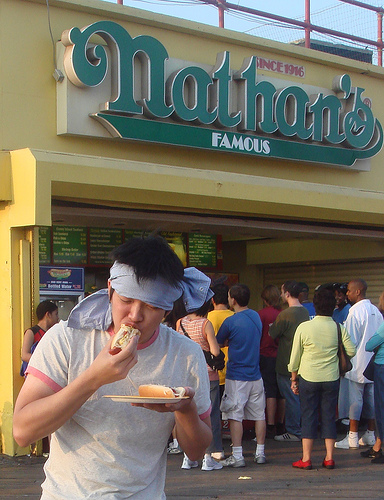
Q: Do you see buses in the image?
A: No, there are no buses.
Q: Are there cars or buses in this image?
A: No, there are no buses or cars.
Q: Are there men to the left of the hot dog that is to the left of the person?
A: Yes, there is a man to the left of the hot dog.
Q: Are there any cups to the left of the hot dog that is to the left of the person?
A: No, there is a man to the left of the hot dog.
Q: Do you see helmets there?
A: No, there are no helmets.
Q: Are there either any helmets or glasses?
A: No, there are no helmets or glasses.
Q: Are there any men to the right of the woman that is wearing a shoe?
A: Yes, there is a man to the right of the woman.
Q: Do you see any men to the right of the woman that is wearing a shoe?
A: Yes, there is a man to the right of the woman.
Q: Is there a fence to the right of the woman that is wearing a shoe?
A: No, there is a man to the right of the woman.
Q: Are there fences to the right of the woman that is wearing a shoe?
A: No, there is a man to the right of the woman.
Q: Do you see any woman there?
A: Yes, there is a woman.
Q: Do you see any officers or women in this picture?
A: Yes, there is a woman.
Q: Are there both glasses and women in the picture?
A: No, there is a woman but no glasses.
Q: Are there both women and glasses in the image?
A: No, there is a woman but no glasses.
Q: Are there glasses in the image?
A: No, there are no glasses.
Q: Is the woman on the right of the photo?
A: Yes, the woman is on the right of the image.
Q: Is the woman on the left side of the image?
A: No, the woman is on the right of the image.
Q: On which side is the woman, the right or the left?
A: The woman is on the right of the image.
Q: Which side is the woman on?
A: The woman is on the right of the image.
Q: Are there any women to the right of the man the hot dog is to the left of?
A: Yes, there is a woman to the right of the man.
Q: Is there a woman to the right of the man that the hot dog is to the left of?
A: Yes, there is a woman to the right of the man.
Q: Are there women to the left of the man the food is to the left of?
A: No, the woman is to the right of the man.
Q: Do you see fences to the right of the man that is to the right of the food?
A: No, there is a woman to the right of the man.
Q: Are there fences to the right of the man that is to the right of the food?
A: No, there is a woman to the right of the man.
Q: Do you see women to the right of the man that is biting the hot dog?
A: Yes, there is a woman to the right of the man.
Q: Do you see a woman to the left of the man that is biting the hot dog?
A: No, the woman is to the right of the man.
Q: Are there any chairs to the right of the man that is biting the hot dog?
A: No, there is a woman to the right of the man.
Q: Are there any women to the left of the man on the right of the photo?
A: Yes, there is a woman to the left of the man.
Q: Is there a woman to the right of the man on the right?
A: No, the woman is to the left of the man.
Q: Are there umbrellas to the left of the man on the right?
A: No, there is a woman to the left of the man.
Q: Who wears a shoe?
A: The woman wears a shoe.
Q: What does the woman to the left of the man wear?
A: The woman wears a shoe.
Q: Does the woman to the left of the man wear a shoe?
A: Yes, the woman wears a shoe.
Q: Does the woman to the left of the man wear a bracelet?
A: No, the woman wears a shoe.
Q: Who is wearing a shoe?
A: The woman is wearing a shoe.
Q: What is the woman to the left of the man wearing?
A: The woman is wearing a shoe.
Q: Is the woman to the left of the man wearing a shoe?
A: Yes, the woman is wearing a shoe.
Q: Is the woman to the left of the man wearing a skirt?
A: No, the woman is wearing a shoe.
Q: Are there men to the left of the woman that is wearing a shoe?
A: Yes, there is a man to the left of the woman.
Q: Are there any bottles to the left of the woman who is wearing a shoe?
A: No, there is a man to the left of the woman.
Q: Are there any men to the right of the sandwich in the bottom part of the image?
A: Yes, there is a man to the right of the sandwich.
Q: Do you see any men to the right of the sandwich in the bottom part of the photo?
A: Yes, there is a man to the right of the sandwich.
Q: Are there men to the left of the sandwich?
A: No, the man is to the right of the sandwich.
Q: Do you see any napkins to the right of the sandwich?
A: No, there is a man to the right of the sandwich.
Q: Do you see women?
A: Yes, there is a woman.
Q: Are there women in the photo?
A: Yes, there is a woman.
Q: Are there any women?
A: Yes, there is a woman.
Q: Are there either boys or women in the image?
A: Yes, there is a woman.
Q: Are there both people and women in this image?
A: Yes, there are both a woman and people.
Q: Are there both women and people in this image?
A: Yes, there are both a woman and people.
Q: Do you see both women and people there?
A: Yes, there are both a woman and people.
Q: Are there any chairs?
A: No, there are no chairs.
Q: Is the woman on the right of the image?
A: Yes, the woman is on the right of the image.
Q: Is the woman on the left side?
A: No, the woman is on the right of the image.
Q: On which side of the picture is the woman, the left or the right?
A: The woman is on the right of the image.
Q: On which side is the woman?
A: The woman is on the right of the image.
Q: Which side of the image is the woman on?
A: The woman is on the right of the image.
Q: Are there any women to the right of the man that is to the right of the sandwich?
A: Yes, there is a woman to the right of the man.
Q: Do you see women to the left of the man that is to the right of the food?
A: No, the woman is to the right of the man.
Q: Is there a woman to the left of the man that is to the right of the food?
A: No, the woman is to the right of the man.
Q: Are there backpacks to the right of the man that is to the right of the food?
A: No, there is a woman to the right of the man.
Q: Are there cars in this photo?
A: No, there are no cars.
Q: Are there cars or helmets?
A: No, there are no cars or helmets.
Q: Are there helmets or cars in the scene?
A: No, there are no cars or helmets.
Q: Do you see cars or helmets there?
A: No, there are no cars or helmets.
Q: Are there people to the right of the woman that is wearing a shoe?
A: Yes, there is a person to the right of the woman.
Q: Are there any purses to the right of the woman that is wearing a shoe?
A: No, there is a person to the right of the woman.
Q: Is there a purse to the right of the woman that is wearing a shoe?
A: No, there is a person to the right of the woman.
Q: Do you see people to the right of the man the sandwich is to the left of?
A: Yes, there is a person to the right of the man.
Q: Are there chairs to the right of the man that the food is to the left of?
A: No, there is a person to the right of the man.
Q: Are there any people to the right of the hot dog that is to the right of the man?
A: Yes, there is a person to the right of the hot dog.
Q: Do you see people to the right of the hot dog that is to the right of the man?
A: Yes, there is a person to the right of the hot dog.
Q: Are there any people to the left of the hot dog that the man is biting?
A: No, the person is to the right of the hot dog.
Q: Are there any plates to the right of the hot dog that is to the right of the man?
A: No, there is a person to the right of the hot dog.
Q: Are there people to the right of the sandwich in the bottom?
A: Yes, there is a person to the right of the sandwich.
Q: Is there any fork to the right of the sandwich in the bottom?
A: No, there is a person to the right of the sandwich.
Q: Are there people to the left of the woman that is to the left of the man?
A: Yes, there is a person to the left of the woman.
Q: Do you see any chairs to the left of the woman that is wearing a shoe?
A: No, there is a person to the left of the woman.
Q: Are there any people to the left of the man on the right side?
A: Yes, there is a person to the left of the man.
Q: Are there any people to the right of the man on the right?
A: No, the person is to the left of the man.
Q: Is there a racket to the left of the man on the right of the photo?
A: No, there is a person to the left of the man.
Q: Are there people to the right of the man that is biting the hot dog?
A: Yes, there is a person to the right of the man.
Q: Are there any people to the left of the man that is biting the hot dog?
A: No, the person is to the right of the man.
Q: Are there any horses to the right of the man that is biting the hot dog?
A: No, there is a person to the right of the man.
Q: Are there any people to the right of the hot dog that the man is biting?
A: Yes, there is a person to the right of the hot dog.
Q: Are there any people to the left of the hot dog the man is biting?
A: No, the person is to the right of the hot dog.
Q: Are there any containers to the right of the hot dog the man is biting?
A: No, there is a person to the right of the hot dog.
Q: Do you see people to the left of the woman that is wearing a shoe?
A: Yes, there is a person to the left of the woman.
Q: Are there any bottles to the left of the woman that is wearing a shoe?
A: No, there is a person to the left of the woman.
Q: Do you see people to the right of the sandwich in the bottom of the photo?
A: Yes, there is a person to the right of the sandwich.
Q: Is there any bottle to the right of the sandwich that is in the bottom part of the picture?
A: No, there is a person to the right of the sandwich.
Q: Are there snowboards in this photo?
A: No, there are no snowboards.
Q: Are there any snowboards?
A: No, there are no snowboards.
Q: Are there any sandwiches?
A: Yes, there is a sandwich.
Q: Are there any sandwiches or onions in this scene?
A: Yes, there is a sandwich.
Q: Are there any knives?
A: No, there are no knives.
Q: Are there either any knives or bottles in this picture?
A: No, there are no knives or bottles.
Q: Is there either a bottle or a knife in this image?
A: No, there are no knives or bottles.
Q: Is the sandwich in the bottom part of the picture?
A: Yes, the sandwich is in the bottom of the image.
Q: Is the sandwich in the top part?
A: No, the sandwich is in the bottom of the image.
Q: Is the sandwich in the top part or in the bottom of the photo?
A: The sandwich is in the bottom of the image.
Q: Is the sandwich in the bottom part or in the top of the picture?
A: The sandwich is in the bottom of the image.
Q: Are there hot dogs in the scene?
A: Yes, there is a hot dog.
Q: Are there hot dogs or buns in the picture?
A: Yes, there is a hot dog.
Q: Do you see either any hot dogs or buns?
A: Yes, there is a hot dog.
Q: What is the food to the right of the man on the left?
A: The food is a hot dog.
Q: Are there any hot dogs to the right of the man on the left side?
A: Yes, there is a hot dog to the right of the man.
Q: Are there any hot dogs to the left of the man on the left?
A: No, the hot dog is to the right of the man.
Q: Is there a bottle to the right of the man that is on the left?
A: No, there is a hot dog to the right of the man.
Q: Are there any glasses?
A: No, there are no glasses.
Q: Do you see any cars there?
A: No, there are no cars.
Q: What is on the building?
A: The sign is on the building.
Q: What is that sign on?
A: The sign is on the building.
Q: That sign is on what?
A: The sign is on the building.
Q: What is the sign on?
A: The sign is on the building.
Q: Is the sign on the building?
A: Yes, the sign is on the building.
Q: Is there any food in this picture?
A: Yes, there is food.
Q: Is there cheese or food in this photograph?
A: Yes, there is food.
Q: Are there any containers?
A: No, there are no containers.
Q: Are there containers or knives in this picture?
A: No, there are no containers or knives.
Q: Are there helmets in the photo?
A: No, there are no helmets.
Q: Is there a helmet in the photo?
A: No, there are no helmets.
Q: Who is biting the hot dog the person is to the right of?
A: The man is biting the hot dog.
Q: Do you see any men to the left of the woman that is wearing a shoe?
A: Yes, there is a man to the left of the woman.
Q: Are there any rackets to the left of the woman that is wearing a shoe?
A: No, there is a man to the left of the woman.